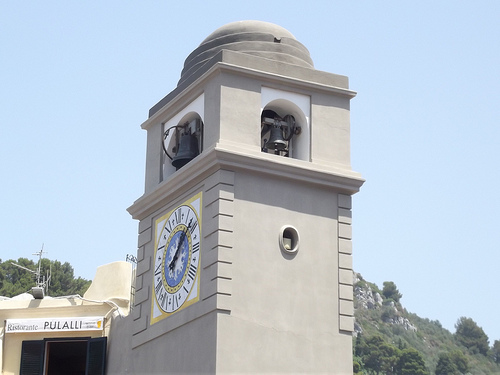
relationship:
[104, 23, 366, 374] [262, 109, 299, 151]
tower has bell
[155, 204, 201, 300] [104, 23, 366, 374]
clock on tower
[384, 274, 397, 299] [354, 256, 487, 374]
tree on hill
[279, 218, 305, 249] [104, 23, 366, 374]
hole on tower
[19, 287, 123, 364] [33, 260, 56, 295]
building has antenna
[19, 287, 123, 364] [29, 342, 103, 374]
building has doorway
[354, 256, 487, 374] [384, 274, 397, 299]
hill has tree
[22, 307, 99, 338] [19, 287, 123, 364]
sign on building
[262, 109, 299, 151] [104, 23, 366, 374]
bell on tower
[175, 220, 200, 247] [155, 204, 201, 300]
hand on clock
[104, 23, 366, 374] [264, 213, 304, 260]
tower has window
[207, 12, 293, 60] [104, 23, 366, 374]
dome on tower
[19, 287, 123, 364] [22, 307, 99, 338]
building has sign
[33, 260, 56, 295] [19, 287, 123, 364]
antenna on building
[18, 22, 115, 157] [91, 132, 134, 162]
sky has clouds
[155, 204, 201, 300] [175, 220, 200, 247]
clock has hand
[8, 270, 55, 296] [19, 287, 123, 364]
tree above building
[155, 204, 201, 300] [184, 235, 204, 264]
clock has roman numerals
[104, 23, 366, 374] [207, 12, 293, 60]
tower has dome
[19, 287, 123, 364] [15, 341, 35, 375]
building has window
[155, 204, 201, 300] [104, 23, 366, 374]
clock in tower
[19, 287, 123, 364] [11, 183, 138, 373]
building in background